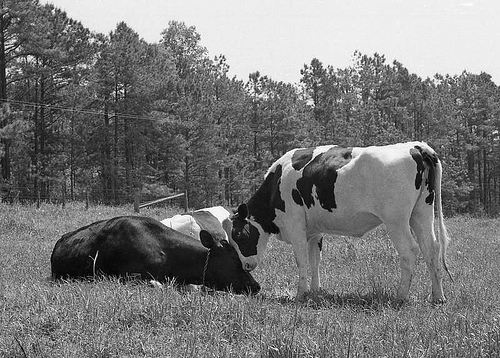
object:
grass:
[1, 190, 498, 356]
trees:
[1, 0, 500, 219]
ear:
[237, 202, 249, 221]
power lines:
[0, 97, 295, 135]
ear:
[199, 230, 219, 250]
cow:
[159, 204, 230, 242]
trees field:
[0, 0, 500, 214]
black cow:
[50, 215, 262, 297]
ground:
[0, 200, 500, 358]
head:
[223, 201, 270, 274]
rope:
[199, 248, 211, 289]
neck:
[174, 236, 212, 284]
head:
[198, 228, 260, 297]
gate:
[132, 184, 189, 213]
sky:
[0, 0, 500, 70]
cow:
[220, 139, 455, 309]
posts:
[0, 186, 199, 213]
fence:
[0, 187, 188, 214]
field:
[0, 199, 500, 358]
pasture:
[0, 156, 500, 358]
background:
[0, 0, 499, 212]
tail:
[417, 142, 457, 285]